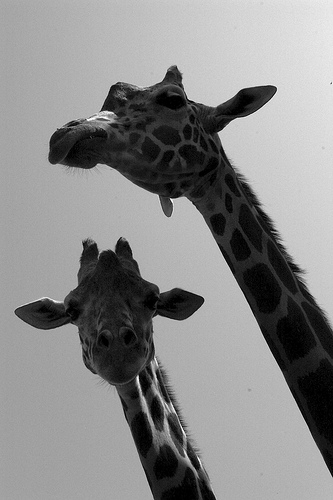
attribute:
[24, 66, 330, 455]
giraffe — taller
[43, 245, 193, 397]
animal — smaller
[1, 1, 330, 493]
photo — black and white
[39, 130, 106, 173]
mouth — dark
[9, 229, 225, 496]
giraffe — smaller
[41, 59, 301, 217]
face — spotted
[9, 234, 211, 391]
face — spotted